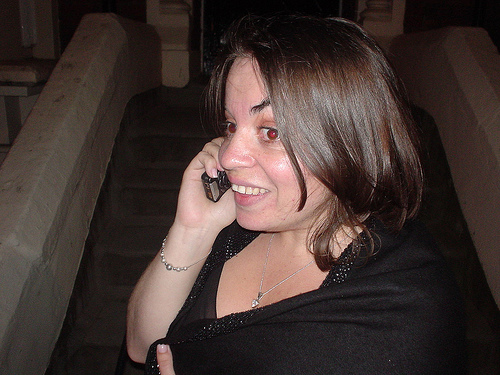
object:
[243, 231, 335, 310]
necklace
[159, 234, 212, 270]
bracelet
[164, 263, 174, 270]
charms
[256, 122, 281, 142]
eye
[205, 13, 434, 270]
hair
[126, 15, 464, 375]
woman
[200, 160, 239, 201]
cell phone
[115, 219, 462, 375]
sweater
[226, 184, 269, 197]
teeth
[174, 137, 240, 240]
hand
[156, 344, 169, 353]
fingernail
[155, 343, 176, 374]
thumb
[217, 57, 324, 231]
face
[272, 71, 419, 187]
light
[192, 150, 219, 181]
fingers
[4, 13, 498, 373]
staircase